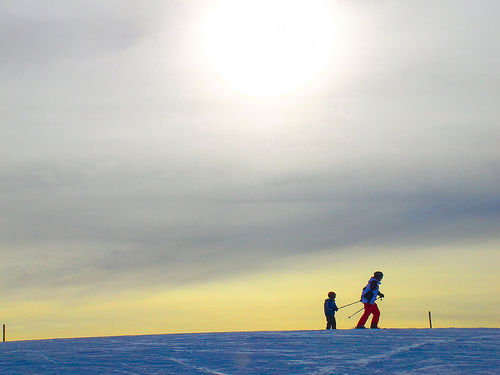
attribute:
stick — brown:
[424, 311, 437, 329]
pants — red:
[358, 303, 380, 326]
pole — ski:
[337, 292, 386, 319]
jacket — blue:
[359, 277, 383, 306]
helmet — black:
[348, 271, 384, 330]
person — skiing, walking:
[379, 291, 384, 299]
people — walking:
[325, 270, 391, 333]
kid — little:
[324, 292, 341, 332]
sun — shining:
[170, 1, 369, 133]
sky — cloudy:
[0, 1, 499, 342]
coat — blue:
[325, 297, 340, 320]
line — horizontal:
[317, 339, 449, 374]